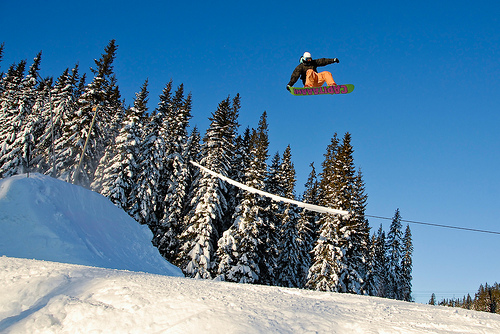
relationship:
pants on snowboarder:
[303, 69, 336, 88] [286, 48, 343, 88]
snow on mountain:
[27, 153, 178, 303] [1, 172, 497, 334]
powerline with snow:
[186, 158, 500, 236] [5, 168, 497, 333]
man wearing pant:
[282, 43, 359, 94] [303, 67, 336, 85]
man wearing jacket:
[282, 43, 359, 94] [281, 55, 335, 86]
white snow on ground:
[1, 174, 498, 332] [0, 244, 497, 332]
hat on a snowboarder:
[302, 52, 311, 61] [284, 49, 340, 85]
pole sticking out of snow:
[59, 81, 139, 210] [5, 168, 497, 333]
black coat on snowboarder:
[288, 56, 334, 86] [284, 50, 341, 88]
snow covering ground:
[0, 253, 498, 334] [2, 253, 497, 318]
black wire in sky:
[363, 211, 499, 242] [11, 7, 484, 187]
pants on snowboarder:
[301, 68, 336, 85] [285, 33, 347, 97]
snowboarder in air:
[286, 52, 364, 105] [189, 12, 487, 113]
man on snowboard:
[282, 43, 359, 94] [282, 82, 357, 93]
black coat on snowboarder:
[287, 56, 337, 84] [283, 50, 355, 95]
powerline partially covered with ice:
[220, 164, 499, 261] [192, 154, 352, 220]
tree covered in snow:
[0, 35, 419, 305] [199, 147, 219, 273]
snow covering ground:
[69, 216, 416, 320] [17, 178, 485, 328]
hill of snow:
[1, 171, 188, 281] [5, 168, 497, 333]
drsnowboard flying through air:
[288, 82, 355, 97] [29, 12, 485, 185]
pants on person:
[303, 69, 336, 88] [281, 42, 346, 93]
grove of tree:
[9, 44, 399, 274] [0, 35, 419, 305]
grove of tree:
[9, 44, 399, 274] [206, 114, 226, 252]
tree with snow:
[0, 35, 419, 305] [281, 296, 397, 320]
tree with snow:
[206, 114, 226, 252] [281, 296, 397, 320]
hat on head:
[301, 53, 308, 60] [296, 50, 316, 68]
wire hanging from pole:
[157, 134, 499, 234] [60, 80, 110, 187]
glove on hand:
[328, 45, 348, 72] [329, 53, 342, 67]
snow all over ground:
[5, 168, 497, 333] [0, 244, 497, 332]